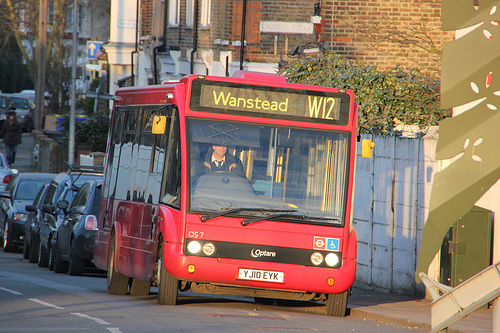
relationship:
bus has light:
[93, 70, 356, 312] [184, 236, 345, 270]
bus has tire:
[93, 70, 356, 312] [151, 249, 180, 305]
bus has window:
[93, 70, 356, 312] [182, 115, 354, 231]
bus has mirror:
[93, 70, 356, 312] [357, 138, 377, 161]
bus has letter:
[93, 70, 356, 312] [213, 89, 341, 123]